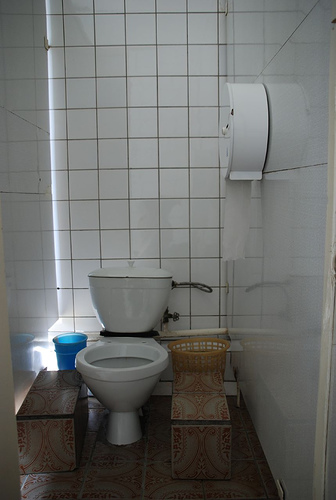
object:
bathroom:
[0, 0, 336, 499]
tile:
[143, 461, 205, 499]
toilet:
[75, 260, 173, 445]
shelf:
[171, 368, 233, 480]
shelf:
[16, 369, 89, 474]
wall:
[0, 14, 336, 499]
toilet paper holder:
[221, 81, 269, 182]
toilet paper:
[222, 178, 251, 262]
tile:
[97, 77, 126, 107]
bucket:
[52, 332, 88, 370]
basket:
[167, 337, 231, 383]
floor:
[16, 394, 280, 500]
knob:
[173, 311, 180, 322]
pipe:
[154, 327, 228, 340]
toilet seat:
[75, 339, 169, 382]